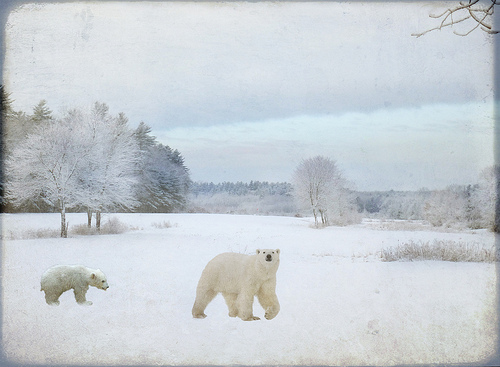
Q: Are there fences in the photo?
A: No, there are no fences.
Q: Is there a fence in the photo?
A: No, there are no fences.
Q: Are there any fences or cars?
A: No, there are no fences or cars.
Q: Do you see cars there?
A: No, there are no cars.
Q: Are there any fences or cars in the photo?
A: No, there are no cars or fences.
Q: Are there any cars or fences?
A: No, there are no cars or fences.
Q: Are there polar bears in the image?
A: Yes, there is a polar bear.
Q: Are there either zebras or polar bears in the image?
A: Yes, there is a polar bear.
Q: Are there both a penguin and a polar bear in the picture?
A: No, there is a polar bear but no penguins.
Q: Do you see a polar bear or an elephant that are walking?
A: Yes, the polar bear is walking.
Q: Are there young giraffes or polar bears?
A: Yes, there is a young polar bear.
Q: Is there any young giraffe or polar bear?
A: Yes, there is a young polar bear.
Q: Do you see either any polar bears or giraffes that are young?
A: Yes, the polar bear is young.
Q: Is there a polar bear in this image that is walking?
A: Yes, there is a polar bear that is walking.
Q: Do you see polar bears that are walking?
A: Yes, there is a polar bear that is walking.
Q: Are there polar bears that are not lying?
A: Yes, there is a polar bear that is walking.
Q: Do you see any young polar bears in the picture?
A: Yes, there is a young polar bear.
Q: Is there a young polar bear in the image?
A: Yes, there is a young polar bear.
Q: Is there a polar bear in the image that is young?
A: Yes, there is a polar bear that is young.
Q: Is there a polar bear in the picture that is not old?
A: Yes, there is an young polar bear.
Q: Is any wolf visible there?
A: No, there are no wolves.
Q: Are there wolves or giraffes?
A: No, there are no wolves or giraffes.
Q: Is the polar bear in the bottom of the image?
A: Yes, the polar bear is in the bottom of the image.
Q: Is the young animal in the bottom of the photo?
A: Yes, the polar bear is in the bottom of the image.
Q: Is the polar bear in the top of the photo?
A: No, the polar bear is in the bottom of the image.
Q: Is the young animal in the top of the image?
A: No, the polar bear is in the bottom of the image.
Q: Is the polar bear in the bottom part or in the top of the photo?
A: The polar bear is in the bottom of the image.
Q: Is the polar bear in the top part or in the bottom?
A: The polar bear is in the bottom of the image.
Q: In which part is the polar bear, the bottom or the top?
A: The polar bear is in the bottom of the image.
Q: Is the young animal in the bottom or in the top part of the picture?
A: The polar bear is in the bottom of the image.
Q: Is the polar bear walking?
A: Yes, the polar bear is walking.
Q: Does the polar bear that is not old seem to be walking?
A: Yes, the polar bear is walking.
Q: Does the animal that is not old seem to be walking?
A: Yes, the polar bear is walking.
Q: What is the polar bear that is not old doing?
A: The polar bear is walking.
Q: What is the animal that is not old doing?
A: The polar bear is walking.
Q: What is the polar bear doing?
A: The polar bear is walking.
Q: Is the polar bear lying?
A: No, the polar bear is walking.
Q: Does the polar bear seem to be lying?
A: No, the polar bear is walking.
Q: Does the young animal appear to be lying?
A: No, the polar bear is walking.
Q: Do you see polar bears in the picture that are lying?
A: No, there is a polar bear but it is walking.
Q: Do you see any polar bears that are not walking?
A: No, there is a polar bear but it is walking.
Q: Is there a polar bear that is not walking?
A: No, there is a polar bear but it is walking.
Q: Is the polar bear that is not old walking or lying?
A: The polar bear is walking.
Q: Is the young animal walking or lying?
A: The polar bear is walking.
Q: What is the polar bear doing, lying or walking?
A: The polar bear is walking.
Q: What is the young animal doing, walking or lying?
A: The polar bear is walking.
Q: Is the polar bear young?
A: Yes, the polar bear is young.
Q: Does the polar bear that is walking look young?
A: Yes, the polar bear is young.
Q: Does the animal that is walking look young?
A: Yes, the polar bear is young.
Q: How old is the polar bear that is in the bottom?
A: The polar bear is young.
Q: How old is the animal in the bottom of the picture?
A: The polar bear is young.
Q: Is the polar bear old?
A: No, the polar bear is young.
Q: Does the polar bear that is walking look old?
A: No, the polar bear is young.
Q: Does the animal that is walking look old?
A: No, the polar bear is young.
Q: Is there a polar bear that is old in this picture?
A: No, there is a polar bear but it is young.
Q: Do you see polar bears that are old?
A: No, there is a polar bear but it is young.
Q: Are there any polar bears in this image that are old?
A: No, there is a polar bear but it is young.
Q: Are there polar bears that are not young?
A: No, there is a polar bear but it is young.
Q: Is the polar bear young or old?
A: The polar bear is young.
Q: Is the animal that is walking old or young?
A: The polar bear is young.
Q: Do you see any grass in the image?
A: Yes, there is grass.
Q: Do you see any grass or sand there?
A: Yes, there is grass.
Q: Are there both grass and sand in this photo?
A: No, there is grass but no sand.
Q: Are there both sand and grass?
A: No, there is grass but no sand.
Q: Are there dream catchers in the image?
A: No, there are no dream catchers.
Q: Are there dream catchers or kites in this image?
A: No, there are no dream catchers or kites.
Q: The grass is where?
A: The grass is on the ground.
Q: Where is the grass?
A: The grass is on the ground.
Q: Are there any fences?
A: No, there are no fences.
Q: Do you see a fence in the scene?
A: No, there are no fences.